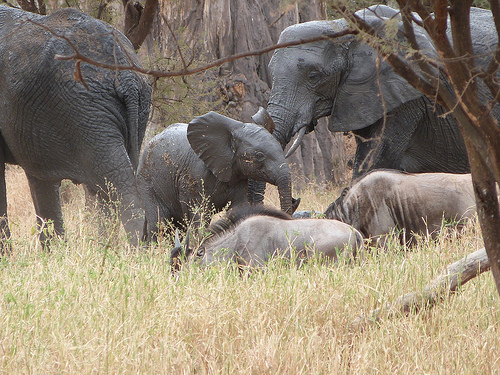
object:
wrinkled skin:
[9, 40, 85, 165]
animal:
[169, 206, 366, 275]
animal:
[327, 170, 480, 250]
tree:
[269, 0, 500, 294]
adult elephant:
[246, 3, 499, 207]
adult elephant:
[0, 1, 148, 253]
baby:
[136, 111, 293, 243]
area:
[6, 13, 480, 368]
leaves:
[383, 19, 400, 49]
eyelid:
[254, 152, 263, 159]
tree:
[118, 0, 160, 51]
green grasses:
[54, 268, 282, 366]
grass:
[0, 165, 500, 375]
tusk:
[283, 125, 306, 159]